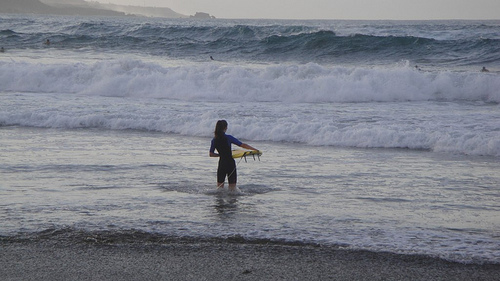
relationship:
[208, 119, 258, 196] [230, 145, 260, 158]
surfer holding surfboard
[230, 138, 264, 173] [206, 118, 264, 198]
surfboard held by surfer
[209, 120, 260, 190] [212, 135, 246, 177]
surfer wearing wetsuit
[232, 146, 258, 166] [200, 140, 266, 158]
rope hanging from surfboard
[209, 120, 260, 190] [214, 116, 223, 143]
surfer wearing ponytail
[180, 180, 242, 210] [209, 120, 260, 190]
ripples around surfer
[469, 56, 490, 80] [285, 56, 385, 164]
person in sea